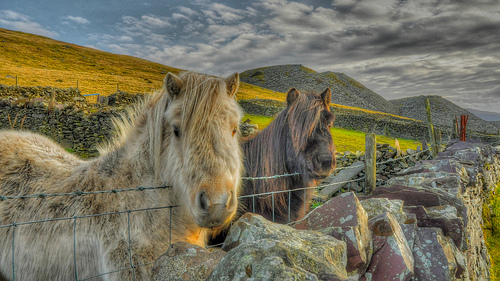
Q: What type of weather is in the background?
A: It is cloudy.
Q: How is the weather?
A: It is cloudy.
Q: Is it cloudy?
A: Yes, it is cloudy.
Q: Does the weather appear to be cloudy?
A: Yes, it is cloudy.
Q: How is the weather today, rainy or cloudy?
A: It is cloudy.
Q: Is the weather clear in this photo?
A: No, it is cloudy.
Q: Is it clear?
A: No, it is cloudy.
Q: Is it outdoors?
A: Yes, it is outdoors.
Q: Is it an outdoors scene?
A: Yes, it is outdoors.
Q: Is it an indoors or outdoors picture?
A: It is outdoors.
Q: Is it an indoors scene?
A: No, it is outdoors.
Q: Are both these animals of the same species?
A: Yes, all the animals are horses.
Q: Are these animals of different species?
A: No, all the animals are horses.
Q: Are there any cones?
A: No, there are no cones.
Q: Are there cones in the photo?
A: No, there are no cones.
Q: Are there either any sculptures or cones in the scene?
A: No, there are no cones or sculptures.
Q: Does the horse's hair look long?
A: Yes, the hair is long.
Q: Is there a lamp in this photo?
A: No, there are no lamps.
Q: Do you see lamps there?
A: No, there are no lamps.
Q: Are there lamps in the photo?
A: No, there are no lamps.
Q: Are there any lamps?
A: No, there are no lamps.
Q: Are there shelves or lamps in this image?
A: No, there are no lamps or shelves.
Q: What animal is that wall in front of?
A: The wall is in front of the horse.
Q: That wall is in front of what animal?
A: The wall is in front of the horse.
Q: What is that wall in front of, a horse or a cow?
A: The wall is in front of a horse.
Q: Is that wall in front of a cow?
A: No, the wall is in front of the horse.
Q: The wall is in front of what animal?
A: The wall is in front of the horse.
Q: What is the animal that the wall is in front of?
A: The animal is a horse.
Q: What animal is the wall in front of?
A: The wall is in front of the horse.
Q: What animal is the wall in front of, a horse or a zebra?
A: The wall is in front of a horse.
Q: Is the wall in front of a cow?
A: No, the wall is in front of the horse.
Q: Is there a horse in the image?
A: Yes, there is a horse.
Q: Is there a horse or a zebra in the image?
A: Yes, there is a horse.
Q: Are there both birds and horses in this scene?
A: No, there is a horse but no birds.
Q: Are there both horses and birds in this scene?
A: No, there is a horse but no birds.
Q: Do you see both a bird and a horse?
A: No, there is a horse but no birds.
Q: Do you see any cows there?
A: No, there are no cows.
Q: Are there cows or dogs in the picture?
A: No, there are no cows or dogs.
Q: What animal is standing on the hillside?
A: The animal is a horse.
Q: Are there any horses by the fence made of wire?
A: Yes, there is a horse by the fence.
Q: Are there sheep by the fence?
A: No, there is a horse by the fence.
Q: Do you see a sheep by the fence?
A: No, there is a horse by the fence.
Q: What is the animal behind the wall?
A: The animal is a horse.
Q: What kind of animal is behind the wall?
A: The animal is a horse.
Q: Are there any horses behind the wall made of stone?
A: Yes, there is a horse behind the wall.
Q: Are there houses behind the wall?
A: No, there is a horse behind the wall.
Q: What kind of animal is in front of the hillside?
A: The animal is a horse.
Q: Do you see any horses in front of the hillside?
A: Yes, there is a horse in front of the hillside.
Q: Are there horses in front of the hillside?
A: Yes, there is a horse in front of the hillside.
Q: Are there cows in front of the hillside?
A: No, there is a horse in front of the hillside.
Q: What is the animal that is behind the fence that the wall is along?
A: The animal is a horse.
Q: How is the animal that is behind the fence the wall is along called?
A: The animal is a horse.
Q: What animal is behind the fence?
A: The animal is a horse.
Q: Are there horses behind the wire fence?
A: Yes, there is a horse behind the fence.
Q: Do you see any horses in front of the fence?
A: No, the horse is behind the fence.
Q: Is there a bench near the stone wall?
A: No, there is a horse near the wall.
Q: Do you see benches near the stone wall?
A: No, there is a horse near the wall.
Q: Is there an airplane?
A: No, there are no airplanes.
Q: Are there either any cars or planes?
A: No, there are no planes or cars.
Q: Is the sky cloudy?
A: Yes, the sky is cloudy.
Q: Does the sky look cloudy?
A: Yes, the sky is cloudy.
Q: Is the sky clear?
A: No, the sky is cloudy.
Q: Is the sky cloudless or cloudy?
A: The sky is cloudy.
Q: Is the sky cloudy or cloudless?
A: The sky is cloudy.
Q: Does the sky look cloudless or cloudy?
A: The sky is cloudy.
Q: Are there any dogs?
A: No, there are no dogs.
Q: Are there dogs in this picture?
A: No, there are no dogs.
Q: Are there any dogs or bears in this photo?
A: No, there are no dogs or bears.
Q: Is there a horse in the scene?
A: Yes, there is a horse.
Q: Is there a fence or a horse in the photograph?
A: Yes, there is a horse.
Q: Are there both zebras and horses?
A: No, there is a horse but no zebras.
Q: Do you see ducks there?
A: No, there are no ducks.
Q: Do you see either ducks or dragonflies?
A: No, there are no ducks or dragonflies.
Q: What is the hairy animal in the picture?
A: The animal is a horse.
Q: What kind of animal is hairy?
A: The animal is a horse.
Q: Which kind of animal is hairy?
A: The animal is a horse.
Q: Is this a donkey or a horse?
A: This is a horse.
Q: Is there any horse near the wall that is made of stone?
A: Yes, there is a horse near the wall.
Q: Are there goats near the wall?
A: No, there is a horse near the wall.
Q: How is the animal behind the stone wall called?
A: The animal is a horse.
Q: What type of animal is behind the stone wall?
A: The animal is a horse.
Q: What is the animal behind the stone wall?
A: The animal is a horse.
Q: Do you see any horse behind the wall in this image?
A: Yes, there is a horse behind the wall.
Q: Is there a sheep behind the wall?
A: No, there is a horse behind the wall.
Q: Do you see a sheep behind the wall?
A: No, there is a horse behind the wall.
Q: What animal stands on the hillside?
A: The horse stands on the hill side.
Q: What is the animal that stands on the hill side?
A: The animal is a horse.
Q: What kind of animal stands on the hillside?
A: The animal is a horse.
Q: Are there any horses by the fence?
A: Yes, there is a horse by the fence.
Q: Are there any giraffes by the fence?
A: No, there is a horse by the fence.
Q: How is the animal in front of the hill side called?
A: The animal is a horse.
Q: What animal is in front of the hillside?
A: The animal is a horse.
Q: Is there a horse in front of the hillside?
A: Yes, there is a horse in front of the hillside.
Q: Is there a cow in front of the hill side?
A: No, there is a horse in front of the hill side.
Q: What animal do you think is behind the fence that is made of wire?
A: The animal is a horse.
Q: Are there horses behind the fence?
A: Yes, there is a horse behind the fence.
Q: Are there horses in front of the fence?
A: No, the horse is behind the fence.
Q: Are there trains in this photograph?
A: No, there are no trains.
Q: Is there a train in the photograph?
A: No, there are no trains.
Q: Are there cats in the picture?
A: No, there are no cats.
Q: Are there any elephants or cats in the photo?
A: No, there are no cats or elephants.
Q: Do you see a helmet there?
A: No, there are no helmets.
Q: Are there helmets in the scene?
A: No, there are no helmets.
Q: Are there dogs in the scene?
A: No, there are no dogs.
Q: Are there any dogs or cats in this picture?
A: No, there are no dogs or cats.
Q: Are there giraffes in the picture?
A: No, there are no giraffes.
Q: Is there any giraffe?
A: No, there are no giraffes.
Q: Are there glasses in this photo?
A: No, there are no glasses.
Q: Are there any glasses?
A: No, there are no glasses.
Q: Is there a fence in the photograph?
A: Yes, there is a fence.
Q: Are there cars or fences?
A: Yes, there is a fence.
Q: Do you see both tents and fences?
A: No, there is a fence but no tents.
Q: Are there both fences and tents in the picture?
A: No, there is a fence but no tents.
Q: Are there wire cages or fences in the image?
A: Yes, there is a wire fence.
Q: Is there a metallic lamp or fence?
A: Yes, there is a metal fence.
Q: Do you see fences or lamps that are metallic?
A: Yes, the fence is metallic.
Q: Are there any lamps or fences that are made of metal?
A: Yes, the fence is made of metal.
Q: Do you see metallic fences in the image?
A: Yes, there is a metal fence.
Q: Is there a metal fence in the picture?
A: Yes, there is a metal fence.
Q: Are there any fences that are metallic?
A: Yes, there is a fence that is metallic.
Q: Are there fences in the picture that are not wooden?
A: Yes, there is a metallic fence.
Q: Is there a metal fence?
A: Yes, there is a fence that is made of metal.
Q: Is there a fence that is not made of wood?
A: Yes, there is a fence that is made of metal.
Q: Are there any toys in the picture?
A: No, there are no toys.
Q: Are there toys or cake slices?
A: No, there are no toys or cake slices.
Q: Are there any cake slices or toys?
A: No, there are no toys or cake slices.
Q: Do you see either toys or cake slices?
A: No, there are no toys or cake slices.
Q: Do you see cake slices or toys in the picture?
A: No, there are no toys or cake slices.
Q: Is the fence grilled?
A: Yes, the fence is grilled.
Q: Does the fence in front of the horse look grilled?
A: Yes, the fence is grilled.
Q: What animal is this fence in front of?
A: The fence is in front of the horse.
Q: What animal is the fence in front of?
A: The fence is in front of the horse.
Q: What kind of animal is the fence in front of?
A: The fence is in front of the horse.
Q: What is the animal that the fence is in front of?
A: The animal is a horse.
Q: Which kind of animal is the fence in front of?
A: The fence is in front of the horse.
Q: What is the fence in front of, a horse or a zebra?
A: The fence is in front of a horse.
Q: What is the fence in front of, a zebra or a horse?
A: The fence is in front of a horse.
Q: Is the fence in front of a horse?
A: Yes, the fence is in front of a horse.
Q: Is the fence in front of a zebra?
A: No, the fence is in front of a horse.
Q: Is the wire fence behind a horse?
A: No, the fence is in front of a horse.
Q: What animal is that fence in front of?
A: The fence is in front of the horse.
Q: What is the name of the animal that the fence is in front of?
A: The animal is a horse.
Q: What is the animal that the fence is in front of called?
A: The animal is a horse.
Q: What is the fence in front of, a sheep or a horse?
A: The fence is in front of a horse.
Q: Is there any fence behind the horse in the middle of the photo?
A: No, the fence is in front of the horse.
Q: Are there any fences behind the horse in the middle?
A: No, the fence is in front of the horse.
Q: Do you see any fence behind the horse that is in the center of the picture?
A: No, the fence is in front of the horse.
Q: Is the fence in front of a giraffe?
A: No, the fence is in front of the horse.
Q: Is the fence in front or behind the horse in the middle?
A: The fence is in front of the horse.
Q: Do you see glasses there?
A: No, there are no glasses.